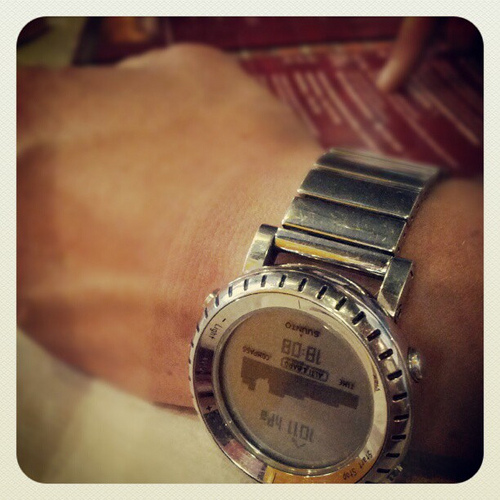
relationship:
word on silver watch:
[204, 318, 224, 340] [185, 147, 445, 483]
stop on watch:
[337, 462, 359, 482] [173, 127, 444, 484]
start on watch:
[348, 450, 385, 471] [190, 160, 466, 489]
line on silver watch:
[240, 277, 250, 291] [185, 147, 445, 483]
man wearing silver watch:
[18, 44, 485, 461] [185, 147, 445, 483]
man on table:
[73, 52, 470, 444] [233, 41, 458, 488]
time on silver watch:
[279, 418, 319, 444] [185, 147, 445, 483]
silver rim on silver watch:
[255, 267, 373, 319] [185, 147, 445, 483]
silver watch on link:
[185, 147, 445, 483] [272, 187, 407, 249]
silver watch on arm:
[185, 147, 445, 483] [16, 37, 499, 475]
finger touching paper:
[364, 24, 416, 109] [293, 51, 368, 121]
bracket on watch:
[245, 151, 441, 291] [136, 197, 436, 483]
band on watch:
[270, 141, 437, 280] [166, 159, 456, 468]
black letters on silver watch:
[278, 338, 322, 367] [185, 147, 445, 483]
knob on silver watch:
[396, 343, 431, 387] [185, 147, 445, 483]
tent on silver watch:
[335, 462, 370, 479] [185, 147, 445, 483]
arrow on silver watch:
[287, 436, 307, 448] [185, 147, 445, 483]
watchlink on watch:
[301, 169, 419, 217] [173, 127, 444, 484]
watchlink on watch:
[323, 146, 420, 181] [173, 127, 444, 484]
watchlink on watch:
[276, 200, 406, 256] [173, 127, 444, 484]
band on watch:
[270, 141, 437, 275] [204, 146, 413, 485]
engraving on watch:
[175, 273, 415, 488] [173, 258, 430, 486]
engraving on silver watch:
[175, 273, 415, 488] [185, 147, 445, 483]